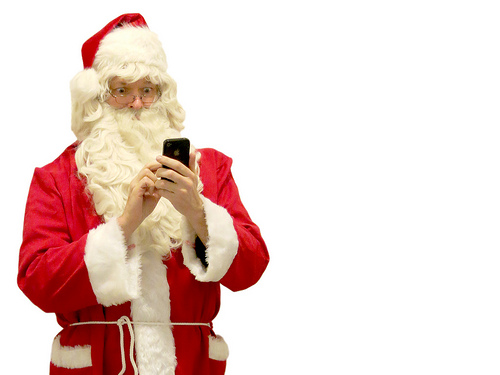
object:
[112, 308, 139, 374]
string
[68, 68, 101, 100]
ball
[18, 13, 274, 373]
man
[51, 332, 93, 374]
pocket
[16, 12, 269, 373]
costume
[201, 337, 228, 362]
trim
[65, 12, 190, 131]
head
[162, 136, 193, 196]
cell phone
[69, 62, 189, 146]
face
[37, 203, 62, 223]
red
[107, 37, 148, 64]
white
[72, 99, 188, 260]
beard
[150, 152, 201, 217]
hand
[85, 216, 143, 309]
cuff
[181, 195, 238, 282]
cuff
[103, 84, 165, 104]
eyeglasses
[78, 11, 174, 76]
cap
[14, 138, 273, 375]
coat